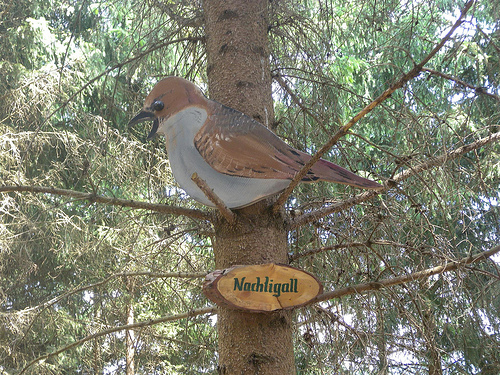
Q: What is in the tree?
A: A bird.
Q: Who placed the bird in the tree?
A: A person.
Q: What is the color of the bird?
A: Brown and white.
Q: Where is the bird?
A: On the tree.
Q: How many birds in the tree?
A: One.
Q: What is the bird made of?
A: Wood.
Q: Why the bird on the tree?
A: For display.